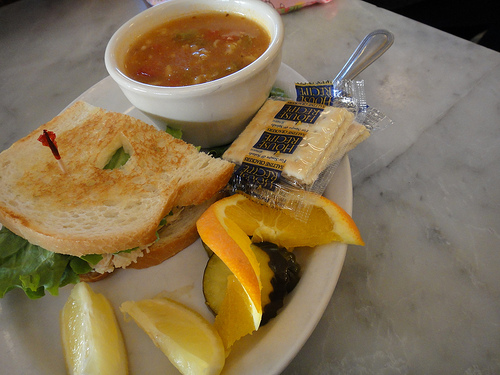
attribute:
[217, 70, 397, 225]
crackers — packed, small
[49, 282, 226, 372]
lemon — sliced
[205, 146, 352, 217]
wrap — plastic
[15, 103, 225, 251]
bread — toasted, white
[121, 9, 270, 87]
soup — dark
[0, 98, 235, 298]
sandwich — toasted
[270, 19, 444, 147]
spoon — silver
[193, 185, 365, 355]
orange slice — sliced, twisted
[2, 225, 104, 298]
lettuce — green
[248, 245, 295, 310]
dill pickle — chunky, sliced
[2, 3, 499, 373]
counter top — White, marbled, white marbled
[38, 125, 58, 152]
plastic curls — red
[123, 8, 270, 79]
soup — tomato based soup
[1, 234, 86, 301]
lettuce — green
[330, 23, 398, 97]
utensil — silver 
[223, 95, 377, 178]
soup crackers — wrapped 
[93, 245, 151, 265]
tuna — toasted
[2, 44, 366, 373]
plate — large, white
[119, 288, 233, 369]
lemon — sliced